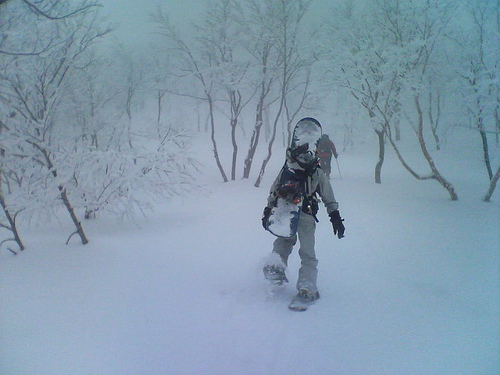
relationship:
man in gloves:
[265, 109, 386, 291] [309, 204, 351, 224]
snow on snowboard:
[286, 295, 307, 311] [282, 290, 323, 315]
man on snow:
[261, 142, 346, 303] [173, 227, 427, 372]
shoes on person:
[251, 253, 333, 307] [237, 130, 390, 270]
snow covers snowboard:
[0, 101, 500, 375] [263, 115, 323, 239]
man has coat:
[261, 142, 346, 303] [297, 170, 337, 213]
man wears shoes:
[261, 142, 346, 303] [259, 261, 326, 313]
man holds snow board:
[261, 142, 346, 303] [257, 108, 324, 246]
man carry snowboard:
[261, 142, 346, 303] [257, 112, 326, 248]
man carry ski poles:
[261, 142, 346, 303] [324, 128, 347, 182]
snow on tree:
[0, 101, 500, 375] [339, 8, 460, 198]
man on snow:
[261, 142, 346, 303] [155, 192, 456, 357]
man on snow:
[261, 142, 346, 303] [186, 214, 409, 350]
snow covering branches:
[0, 101, 500, 375] [47, 64, 179, 219]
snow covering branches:
[0, 101, 500, 375] [62, 126, 171, 196]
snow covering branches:
[0, 101, 500, 375] [354, 29, 455, 200]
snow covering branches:
[0, 101, 500, 375] [196, 30, 299, 112]